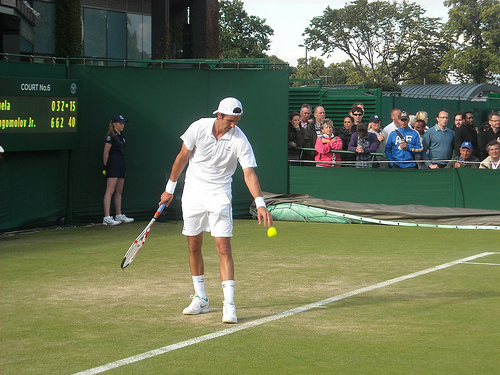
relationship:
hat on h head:
[209, 97, 243, 110] [211, 99, 240, 134]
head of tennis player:
[211, 99, 240, 134] [156, 94, 274, 324]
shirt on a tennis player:
[179, 120, 262, 199] [156, 94, 274, 324]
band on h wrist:
[254, 194, 270, 210] [247, 190, 266, 209]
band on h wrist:
[165, 180, 177, 192] [163, 171, 178, 193]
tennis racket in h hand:
[115, 204, 171, 274] [160, 196, 175, 205]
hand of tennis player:
[160, 196, 175, 205] [156, 94, 274, 324]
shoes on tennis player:
[184, 295, 238, 323] [156, 94, 274, 324]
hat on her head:
[115, 116, 128, 122] [113, 118, 126, 133]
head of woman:
[113, 118, 126, 133] [97, 112, 145, 226]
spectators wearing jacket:
[385, 114, 425, 168] [382, 129, 423, 165]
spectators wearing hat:
[385, 114, 425, 168] [398, 111, 409, 122]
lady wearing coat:
[312, 119, 343, 164] [314, 136, 344, 165]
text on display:
[1, 97, 76, 133] [2, 77, 79, 154]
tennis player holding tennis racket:
[156, 94, 274, 324] [115, 204, 171, 274]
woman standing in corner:
[97, 112, 145, 226] [69, 72, 152, 228]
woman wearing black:
[97, 112, 145, 226] [103, 131, 126, 178]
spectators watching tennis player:
[287, 99, 499, 168] [156, 94, 274, 324]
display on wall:
[2, 77, 79, 154] [2, 62, 82, 229]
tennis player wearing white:
[156, 94, 274, 324] [177, 119, 254, 243]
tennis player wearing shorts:
[156, 94, 274, 324] [181, 204, 235, 236]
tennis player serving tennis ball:
[156, 94, 274, 324] [268, 225, 280, 239]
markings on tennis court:
[56, 248, 500, 375] [4, 213, 495, 374]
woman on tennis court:
[97, 112, 145, 226] [4, 213, 495, 374]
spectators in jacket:
[385, 114, 425, 168] [382, 129, 423, 165]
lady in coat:
[312, 119, 343, 164] [314, 136, 344, 165]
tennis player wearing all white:
[156, 94, 274, 324] [177, 119, 254, 243]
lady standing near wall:
[312, 119, 343, 164] [2, 62, 82, 229]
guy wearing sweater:
[426, 112, 455, 170] [424, 126, 455, 162]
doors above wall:
[81, 7, 151, 66] [4, 59, 285, 224]